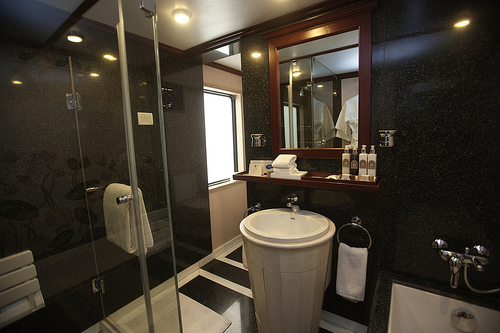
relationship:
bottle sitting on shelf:
[340, 144, 350, 181] [231, 165, 384, 194]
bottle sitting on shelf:
[340, 144, 350, 181] [227, 169, 382, 186]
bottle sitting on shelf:
[333, 143, 349, 180] [236, 158, 385, 188]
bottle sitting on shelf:
[340, 144, 350, 181] [230, 160, 380, 190]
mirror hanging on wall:
[276, 29, 360, 149] [235, 2, 496, 330]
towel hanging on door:
[101, 182, 156, 257] [2, 0, 182, 329]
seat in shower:
[0, 241, 53, 321] [2, 0, 186, 330]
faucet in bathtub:
[371, 231, 498, 331] [369, 267, 497, 331]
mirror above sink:
[276, 29, 360, 149] [274, 144, 361, 192]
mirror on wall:
[269, 44, 363, 146] [237, 37, 497, 296]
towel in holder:
[311, 212, 412, 296] [319, 189, 405, 272]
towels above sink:
[270, 154, 305, 179] [233, 200, 333, 332]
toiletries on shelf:
[339, 145, 376, 176] [231, 169, 379, 189]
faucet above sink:
[275, 192, 301, 211] [233, 200, 333, 332]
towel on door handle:
[92, 178, 161, 266] [109, 189, 137, 213]